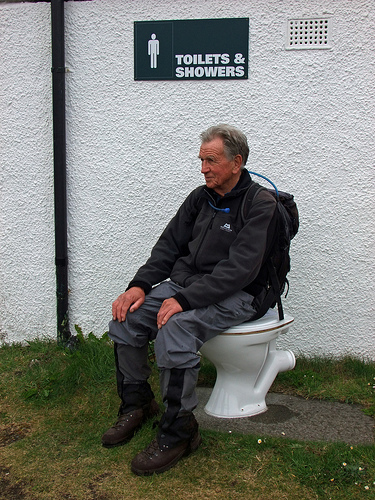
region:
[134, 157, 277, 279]
man wearing a gray sweater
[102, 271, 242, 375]
man wearing gray pants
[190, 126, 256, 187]
man with gray hair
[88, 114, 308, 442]
Man sitting on a toilet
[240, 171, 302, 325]
man wearing a backpack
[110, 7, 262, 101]
a sign on a wall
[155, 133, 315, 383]
a man sitting on a toilet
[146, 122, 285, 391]
a man sitting on a white toilet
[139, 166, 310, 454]
a toilet that is outside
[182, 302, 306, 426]
a white toilet that is outside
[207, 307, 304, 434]
a bathroom toilet that is outside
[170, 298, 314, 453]
a white bathroom toilet outside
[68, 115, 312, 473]
this is a man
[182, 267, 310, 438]
this is a toilet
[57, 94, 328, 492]
man sitting on the toilet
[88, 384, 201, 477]
man wearing lace up boots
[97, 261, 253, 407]
a man wearing a grey shirt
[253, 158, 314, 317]
backpack on mans back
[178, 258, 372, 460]
toilet on a patch of cement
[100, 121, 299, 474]
Elderly man resting on toilet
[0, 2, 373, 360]
White building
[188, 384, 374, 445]
Small concrete pad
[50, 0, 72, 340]
Long black pipe on side of building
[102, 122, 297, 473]
Man wearing a back pack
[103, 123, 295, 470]
Elderly man with graying hair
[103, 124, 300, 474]
Man wearing a black jacket and brown shoes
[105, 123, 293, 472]
Elderly man wearing brown boots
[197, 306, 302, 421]
a white porcelain toilet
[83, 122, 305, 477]
a grey haired man sitting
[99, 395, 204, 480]
brown leather lace-upboots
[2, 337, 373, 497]
a lawn with bare spots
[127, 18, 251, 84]
a sign saying toilets and showers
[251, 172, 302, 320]
a dark color backpack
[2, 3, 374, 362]
a textured white wall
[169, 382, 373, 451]
some dark asphalt under the toilet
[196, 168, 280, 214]
blue wraparound microphone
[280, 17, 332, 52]
a white wall vent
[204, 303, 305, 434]
the toilet is outdoor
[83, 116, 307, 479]
man sitting on a toilet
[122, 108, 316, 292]
old man has gray hair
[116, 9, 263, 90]
a sign for toilets and showers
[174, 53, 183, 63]
white letter on sign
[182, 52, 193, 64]
white letter on sign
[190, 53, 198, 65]
white letter on sign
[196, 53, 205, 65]
white letter on sign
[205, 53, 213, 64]
white letter on sign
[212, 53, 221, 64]
white letter on sign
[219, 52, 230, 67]
white letter on sign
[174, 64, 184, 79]
white letter on sign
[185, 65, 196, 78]
white letter on sign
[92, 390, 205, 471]
man wearing brown boots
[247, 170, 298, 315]
man wearing black backpack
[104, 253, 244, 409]
man wearing gray pants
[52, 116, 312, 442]
man sitting on a toilet